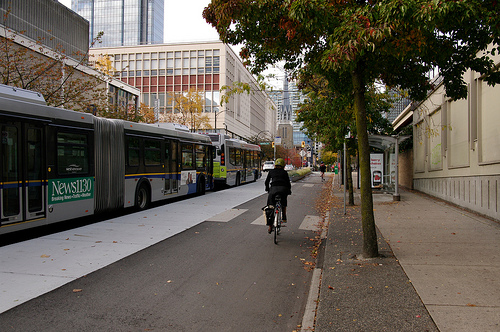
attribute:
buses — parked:
[3, 82, 260, 211]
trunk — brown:
[347, 88, 390, 266]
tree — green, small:
[216, 1, 443, 280]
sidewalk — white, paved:
[18, 215, 176, 277]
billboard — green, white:
[48, 172, 106, 204]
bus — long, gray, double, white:
[2, 87, 108, 224]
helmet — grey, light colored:
[275, 156, 288, 167]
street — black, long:
[2, 48, 242, 270]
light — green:
[250, 133, 264, 152]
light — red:
[218, 153, 225, 170]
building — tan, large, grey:
[2, 3, 150, 114]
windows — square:
[137, 56, 217, 92]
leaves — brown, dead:
[304, 227, 320, 273]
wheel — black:
[134, 181, 155, 207]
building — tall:
[276, 55, 309, 125]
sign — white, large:
[369, 150, 397, 197]